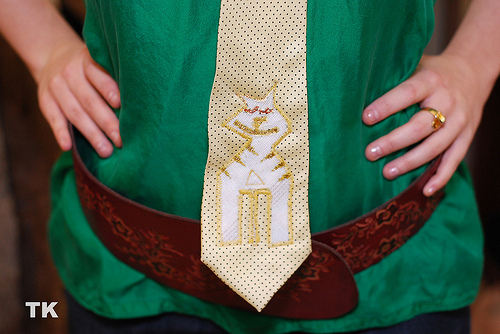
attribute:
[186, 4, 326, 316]
cat tie — yellow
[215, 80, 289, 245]
cat — square shaped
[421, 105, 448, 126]
ring — yellow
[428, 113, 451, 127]
jewel — yellow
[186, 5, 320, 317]
tie — dotted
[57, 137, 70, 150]
fingernail — short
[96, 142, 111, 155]
fingernail — short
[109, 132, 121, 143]
fingernail — short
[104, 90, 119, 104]
fingernail — short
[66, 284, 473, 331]
jeans — blue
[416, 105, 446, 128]
ring — silvery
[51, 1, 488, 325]
top — green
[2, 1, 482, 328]
person — emerald green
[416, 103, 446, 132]
ring — gold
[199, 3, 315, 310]
tie — funny, yellow, gold, dotted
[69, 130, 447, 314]
belt — brown, leather, flower patterned, nice, crafted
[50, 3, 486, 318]
shirt — green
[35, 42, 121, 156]
hand — bare, right hand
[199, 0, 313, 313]
polka dots — black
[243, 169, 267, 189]
triangle — small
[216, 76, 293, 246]
insignia — white, gold, cat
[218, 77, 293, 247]
design — cat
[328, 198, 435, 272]
design — floral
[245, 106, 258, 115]
eye — red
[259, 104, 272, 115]
eye — red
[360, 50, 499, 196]
hand — left hand